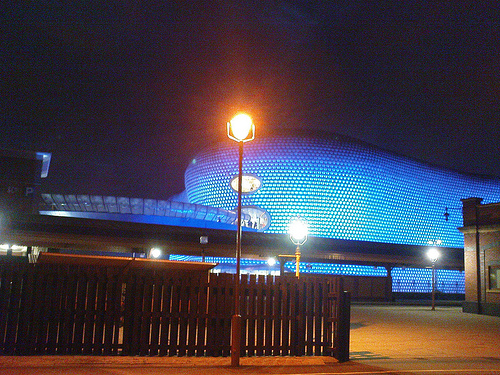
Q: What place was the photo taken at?
A: It was taken at the walkway.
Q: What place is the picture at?
A: It is at the walkway.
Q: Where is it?
A: This is at the walkway.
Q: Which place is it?
A: It is a walkway.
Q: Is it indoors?
A: Yes, it is indoors.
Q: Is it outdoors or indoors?
A: It is indoors.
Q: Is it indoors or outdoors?
A: It is indoors.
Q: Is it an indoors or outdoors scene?
A: It is indoors.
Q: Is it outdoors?
A: No, it is indoors.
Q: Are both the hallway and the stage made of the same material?
A: Yes, both the hallway and the stage are made of glass.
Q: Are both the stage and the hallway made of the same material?
A: Yes, both the stage and the hallway are made of glass.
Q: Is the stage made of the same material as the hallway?
A: Yes, both the stage and the hallway are made of glass.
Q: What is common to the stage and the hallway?
A: The material, both the stage and the hallway are glass.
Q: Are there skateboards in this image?
A: No, there are no skateboards.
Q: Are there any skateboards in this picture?
A: No, there are no skateboards.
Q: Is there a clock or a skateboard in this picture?
A: No, there are no skateboards or clocks.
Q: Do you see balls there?
A: No, there are no balls.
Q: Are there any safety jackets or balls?
A: No, there are no balls or safety jackets.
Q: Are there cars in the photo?
A: No, there are no cars.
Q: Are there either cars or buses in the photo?
A: No, there are no cars or buses.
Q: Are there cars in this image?
A: No, there are no cars.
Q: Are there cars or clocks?
A: No, there are no cars or clocks.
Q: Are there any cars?
A: No, there are no cars.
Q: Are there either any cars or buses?
A: No, there are no cars or buses.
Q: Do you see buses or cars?
A: No, there are no cars or buses.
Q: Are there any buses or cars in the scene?
A: No, there are no cars or buses.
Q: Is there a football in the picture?
A: No, there are no footballs.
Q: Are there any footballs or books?
A: No, there are no footballs or books.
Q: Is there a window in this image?
A: Yes, there is a window.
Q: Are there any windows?
A: Yes, there is a window.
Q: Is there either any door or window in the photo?
A: Yes, there is a window.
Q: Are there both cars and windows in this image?
A: No, there is a window but no cars.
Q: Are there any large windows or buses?
A: Yes, there is a large window.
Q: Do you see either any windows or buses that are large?
A: Yes, the window is large.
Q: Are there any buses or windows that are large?
A: Yes, the window is large.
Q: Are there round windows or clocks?
A: Yes, there is a round window.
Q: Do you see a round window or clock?
A: Yes, there is a round window.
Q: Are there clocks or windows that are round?
A: Yes, the window is round.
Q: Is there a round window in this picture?
A: Yes, there is a round window.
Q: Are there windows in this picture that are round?
A: Yes, there is a window that is round.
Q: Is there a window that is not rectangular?
A: Yes, there is a round window.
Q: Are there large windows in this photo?
A: Yes, there is a large window.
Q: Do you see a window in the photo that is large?
A: Yes, there is a window that is large.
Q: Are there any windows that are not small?
A: Yes, there is a large window.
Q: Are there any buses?
A: No, there are no buses.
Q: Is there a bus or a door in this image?
A: No, there are no buses or doors.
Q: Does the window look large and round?
A: Yes, the window is large and round.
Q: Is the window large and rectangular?
A: No, the window is large but round.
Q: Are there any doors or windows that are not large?
A: No, there is a window but it is large.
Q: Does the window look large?
A: Yes, the window is large.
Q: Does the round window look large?
A: Yes, the window is large.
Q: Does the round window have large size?
A: Yes, the window is large.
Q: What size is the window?
A: The window is large.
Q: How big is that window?
A: The window is large.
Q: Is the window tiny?
A: No, the window is large.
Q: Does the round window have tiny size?
A: No, the window is large.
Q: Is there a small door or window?
A: No, there is a window but it is large.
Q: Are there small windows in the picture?
A: No, there is a window but it is large.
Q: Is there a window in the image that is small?
A: No, there is a window but it is large.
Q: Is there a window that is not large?
A: No, there is a window but it is large.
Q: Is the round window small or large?
A: The window is large.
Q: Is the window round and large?
A: Yes, the window is round and large.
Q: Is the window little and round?
A: No, the window is round but large.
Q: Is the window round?
A: Yes, the window is round.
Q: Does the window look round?
A: Yes, the window is round.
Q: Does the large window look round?
A: Yes, the window is round.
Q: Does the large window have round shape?
A: Yes, the window is round.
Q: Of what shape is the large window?
A: The window is round.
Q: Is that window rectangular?
A: No, the window is round.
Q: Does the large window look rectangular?
A: No, the window is round.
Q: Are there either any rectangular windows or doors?
A: No, there is a window but it is round.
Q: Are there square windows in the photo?
A: No, there is a window but it is round.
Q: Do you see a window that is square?
A: No, there is a window but it is round.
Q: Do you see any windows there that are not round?
A: No, there is a window but it is round.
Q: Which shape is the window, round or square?
A: The window is round.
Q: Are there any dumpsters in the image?
A: No, there are no dumpsters.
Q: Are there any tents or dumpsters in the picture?
A: No, there are no dumpsters or tents.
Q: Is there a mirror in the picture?
A: No, there are no mirrors.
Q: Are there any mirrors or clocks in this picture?
A: No, there are no mirrors or clocks.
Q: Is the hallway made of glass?
A: Yes, the hallway is made of glass.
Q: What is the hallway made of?
A: The hallway is made of glass.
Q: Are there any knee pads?
A: No, there are no knee pads.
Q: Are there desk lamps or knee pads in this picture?
A: No, there are no knee pads or desk lamps.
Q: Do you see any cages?
A: No, there are no cages.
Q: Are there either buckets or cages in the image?
A: No, there are no cages or buckets.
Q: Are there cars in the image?
A: No, there are no cars.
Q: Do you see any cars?
A: No, there are no cars.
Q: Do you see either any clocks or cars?
A: No, there are no cars or clocks.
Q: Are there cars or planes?
A: No, there are no cars or planes.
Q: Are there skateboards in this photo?
A: No, there are no skateboards.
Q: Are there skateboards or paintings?
A: No, there are no skateboards or paintings.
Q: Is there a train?
A: No, there are no trains.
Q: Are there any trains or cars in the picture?
A: No, there are no trains or cars.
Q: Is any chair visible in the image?
A: No, there are no chairs.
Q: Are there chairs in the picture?
A: No, there are no chairs.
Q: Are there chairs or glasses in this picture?
A: No, there are no chairs or glasses.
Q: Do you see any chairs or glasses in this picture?
A: No, there are no chairs or glasses.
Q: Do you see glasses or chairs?
A: No, there are no chairs or glasses.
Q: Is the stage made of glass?
A: Yes, the stage is made of glass.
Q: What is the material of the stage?
A: The stage is made of glass.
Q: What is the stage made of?
A: The stage is made of glass.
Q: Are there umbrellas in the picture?
A: No, there are no umbrellas.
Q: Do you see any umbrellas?
A: No, there are no umbrellas.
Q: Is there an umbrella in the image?
A: No, there are no umbrellas.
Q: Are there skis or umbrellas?
A: No, there are no umbrellas or skis.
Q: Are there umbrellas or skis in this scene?
A: No, there are no umbrellas or skis.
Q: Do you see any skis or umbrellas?
A: No, there are no umbrellas or skis.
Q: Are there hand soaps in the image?
A: No, there are no hand soaps.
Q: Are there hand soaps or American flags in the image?
A: No, there are no hand soaps or American flags.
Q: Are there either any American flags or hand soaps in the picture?
A: No, there are no hand soaps or American flags.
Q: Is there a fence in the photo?
A: Yes, there is a fence.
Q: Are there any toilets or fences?
A: Yes, there is a fence.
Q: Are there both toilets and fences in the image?
A: No, there is a fence but no toilets.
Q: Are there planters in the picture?
A: No, there are no planters.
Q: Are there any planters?
A: No, there are no planters.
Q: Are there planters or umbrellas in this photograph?
A: No, there are no planters or umbrellas.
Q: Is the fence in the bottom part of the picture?
A: Yes, the fence is in the bottom of the image.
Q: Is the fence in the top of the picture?
A: No, the fence is in the bottom of the image.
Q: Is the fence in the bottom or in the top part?
A: The fence is in the bottom of the image.